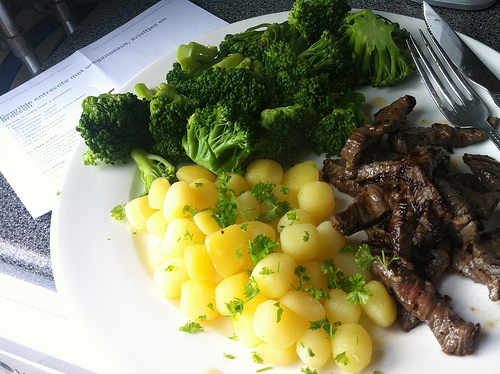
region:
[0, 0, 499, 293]
a gray countertop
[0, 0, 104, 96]
a blue and white floor in the background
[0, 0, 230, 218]
a piece of paper on the counter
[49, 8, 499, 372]
a white round plate of food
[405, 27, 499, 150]
a fork on the plate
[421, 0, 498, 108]
a knife on the plate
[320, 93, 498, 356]
a portion of meat on the plate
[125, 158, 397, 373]
a portion of pasta on the plate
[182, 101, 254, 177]
a piece of broccoli on the plate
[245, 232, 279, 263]
a green herb on the plate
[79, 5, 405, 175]
green steamed broccoli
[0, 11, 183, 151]
a recipe for Gegrilde entrecote met oreganosaus, krieltjes en broccoli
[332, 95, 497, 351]
steak cut into strips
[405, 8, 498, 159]
a knife and a fork on a plate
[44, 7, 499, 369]
a meal on a white plate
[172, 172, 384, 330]
thinly chopped oregano garnishing a dish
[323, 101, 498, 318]
grilled meat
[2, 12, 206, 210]
a printed out recipe for a meal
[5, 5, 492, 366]
homecooked food, made from a recipe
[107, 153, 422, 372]
tiny potatoes on a meal plate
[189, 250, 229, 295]
Potatoes on a plate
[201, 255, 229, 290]
Peeled potatoes on a plate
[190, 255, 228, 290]
Cooked potatoes on a plate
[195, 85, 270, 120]
Greens on a plate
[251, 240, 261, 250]
Celery leaves on potatoes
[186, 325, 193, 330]
A leaf on the plate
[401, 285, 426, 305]
Meat on a plate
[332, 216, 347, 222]
Meat touching a potato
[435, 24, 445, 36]
A knife on a plate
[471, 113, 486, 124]
A fork on a piece of meat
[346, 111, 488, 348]
the meat is brown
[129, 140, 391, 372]
the potatoes are yellow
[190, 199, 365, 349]
the potatoes are yellow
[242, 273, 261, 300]
piece of green parsley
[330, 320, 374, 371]
little round boiled potato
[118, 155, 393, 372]
boiled potatoes with parsley on them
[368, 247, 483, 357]
a piece of grilled steak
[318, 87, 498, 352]
grilled steak cut into pieces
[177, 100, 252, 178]
a piece of green broccoli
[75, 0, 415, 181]
a bunch of cooked pieces of broccoli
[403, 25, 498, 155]
a silver fork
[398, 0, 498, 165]
silver fork and knife on a plate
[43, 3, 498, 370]
white round plate with potatoes broccoli and steak on it